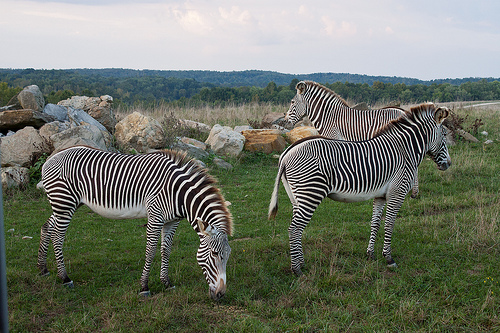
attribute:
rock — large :
[167, 134, 205, 155]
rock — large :
[19, 76, 170, 157]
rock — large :
[206, 114, 245, 166]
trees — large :
[1, 60, 288, 102]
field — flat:
[426, 233, 488, 320]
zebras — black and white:
[34, 143, 236, 307]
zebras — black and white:
[265, 98, 452, 284]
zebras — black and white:
[280, 77, 423, 200]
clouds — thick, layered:
[1, 0, 488, 82]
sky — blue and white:
[2, 1, 494, 67]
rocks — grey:
[6, 104, 271, 154]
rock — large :
[43, 103, 69, 120]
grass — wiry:
[321, 245, 471, 320]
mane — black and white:
[362, 102, 442, 147]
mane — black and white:
[302, 75, 350, 110]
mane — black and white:
[152, 143, 234, 238]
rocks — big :
[0, 84, 329, 189]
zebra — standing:
[264, 101, 452, 263]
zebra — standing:
[274, 76, 408, 144]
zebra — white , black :
[25, 142, 246, 294]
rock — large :
[110, 111, 165, 149]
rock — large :
[201, 122, 248, 165]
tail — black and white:
[256, 152, 288, 216]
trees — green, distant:
[154, 81, 439, 113]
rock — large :
[3, 118, 44, 195]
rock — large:
[115, 110, 165, 152]